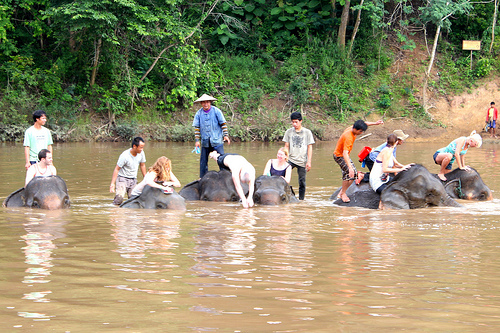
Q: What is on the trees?
A: Green leaves.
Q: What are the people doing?
A: Riding elephants.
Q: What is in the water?
A: A reflection.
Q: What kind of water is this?
A: Dirty and muddy.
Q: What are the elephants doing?
A: Carrying people.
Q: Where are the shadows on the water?
A: In the water.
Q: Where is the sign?
A: On the right side path.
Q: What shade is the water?
A: Brown.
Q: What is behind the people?
A: Trees.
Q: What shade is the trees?
A: Green.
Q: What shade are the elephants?
A: Gray.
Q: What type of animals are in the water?
A: Elephants.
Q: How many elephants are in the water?
A: 6.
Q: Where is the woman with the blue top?
A: On the elephant.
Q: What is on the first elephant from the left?
A: A man.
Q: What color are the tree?
A: Green.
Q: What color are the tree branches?
A: Brown.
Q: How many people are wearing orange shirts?
A: 1.